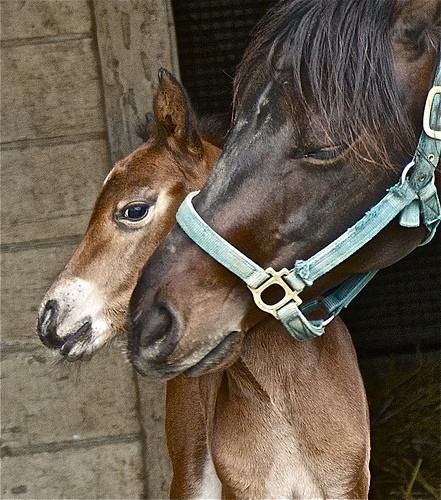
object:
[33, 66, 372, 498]
foal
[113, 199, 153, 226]
eye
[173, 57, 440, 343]
bridle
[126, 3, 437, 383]
horse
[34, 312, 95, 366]
mouth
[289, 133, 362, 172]
eye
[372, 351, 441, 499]
straw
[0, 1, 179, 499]
boards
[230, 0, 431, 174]
mane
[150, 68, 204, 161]
ears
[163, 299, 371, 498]
body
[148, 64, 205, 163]
ear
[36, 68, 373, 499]
calf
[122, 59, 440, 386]
reigns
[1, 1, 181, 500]
wall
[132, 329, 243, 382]
mouth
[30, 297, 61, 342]
nose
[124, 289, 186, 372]
nose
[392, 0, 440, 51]
ear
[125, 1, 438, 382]
head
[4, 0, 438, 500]
barn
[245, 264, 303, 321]
harness